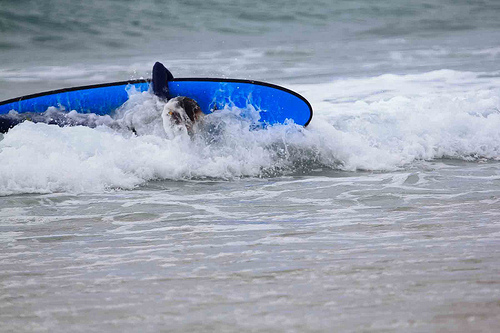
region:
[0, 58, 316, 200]
a blue surfboard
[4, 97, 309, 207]
a splash of water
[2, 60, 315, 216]
a blue surfboard in the water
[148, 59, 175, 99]
an arm on the surfboard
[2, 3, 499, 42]
body of water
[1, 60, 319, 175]
a person fell off the surfboard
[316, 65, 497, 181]
a water formed into a wave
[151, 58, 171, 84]
an elbow of the person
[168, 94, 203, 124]
a head of the person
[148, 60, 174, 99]
an arm with blue swimsuit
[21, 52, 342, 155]
surfer with blue board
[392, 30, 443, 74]
white clouds in blue sky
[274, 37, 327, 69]
white clouds in blue sky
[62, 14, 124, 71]
white clouds in blue sky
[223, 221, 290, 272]
white clouds in blue sky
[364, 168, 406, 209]
white clouds in blue sky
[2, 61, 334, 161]
The surfboard is blue.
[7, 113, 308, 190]
The waves are rough.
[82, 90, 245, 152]
The surfer can't be seen.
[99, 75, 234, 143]
The surfer is under water.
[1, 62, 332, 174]
The surfboard is on its' side.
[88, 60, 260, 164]
The surfer is next to the surfboard.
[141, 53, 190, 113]
The surfer is wearing a blue shirt.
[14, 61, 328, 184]
The surfboard is inside the water.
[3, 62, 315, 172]
The surfer is trying to get back on the surfboard.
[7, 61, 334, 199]
The surfer fell off the surfboard.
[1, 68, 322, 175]
Black and blue surfboard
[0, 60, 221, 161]
Person riding surfboard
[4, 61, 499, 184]
White ocean foam on wave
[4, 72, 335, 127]
Black outline on blue surfboard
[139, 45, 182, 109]
Persons arm hanging over surfboard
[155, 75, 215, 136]
Person with dark hair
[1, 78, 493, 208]
Small white ocean wave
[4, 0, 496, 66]
Ripples in the water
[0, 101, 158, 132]
Black pants on surfer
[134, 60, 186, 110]
Blue sleeve on person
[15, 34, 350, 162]
Surfer wiped out in the ocean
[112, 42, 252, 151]
Mans hand holding on to board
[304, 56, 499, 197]
The water has white foam on it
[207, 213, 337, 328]
The water is very clear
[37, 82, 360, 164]
The surfboard is blue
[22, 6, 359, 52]
The waves are behind the surfboard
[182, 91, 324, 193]
Water spraying up in the air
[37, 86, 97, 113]
Water on the surfboard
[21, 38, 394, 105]
Surfboard is on its side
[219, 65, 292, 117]
Black lining on the board